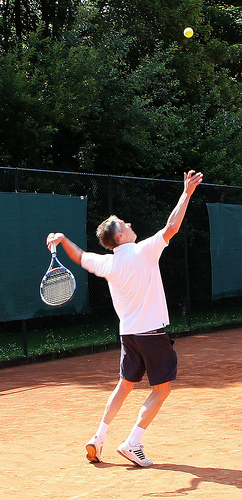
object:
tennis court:
[0, 323, 241, 500]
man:
[44, 167, 203, 470]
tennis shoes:
[117, 438, 154, 470]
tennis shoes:
[86, 435, 103, 464]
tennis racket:
[38, 240, 76, 306]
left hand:
[46, 231, 64, 252]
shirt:
[80, 230, 170, 335]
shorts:
[119, 326, 179, 387]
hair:
[95, 214, 120, 250]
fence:
[1, 164, 240, 367]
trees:
[66, 0, 170, 203]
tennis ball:
[184, 25, 196, 39]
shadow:
[92, 460, 242, 499]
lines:
[134, 449, 143, 454]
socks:
[127, 425, 146, 448]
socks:
[96, 422, 110, 439]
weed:
[179, 298, 202, 334]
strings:
[48, 276, 62, 300]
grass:
[0, 303, 240, 369]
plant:
[45, 328, 72, 356]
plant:
[0, 341, 30, 365]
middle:
[51, 264, 61, 273]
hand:
[182, 168, 203, 195]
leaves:
[8, 39, 32, 83]